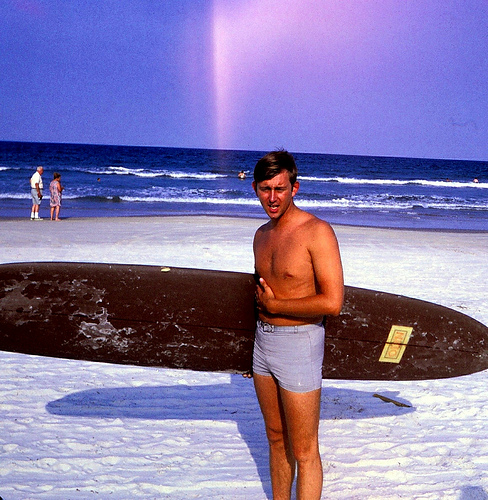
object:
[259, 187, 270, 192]
eye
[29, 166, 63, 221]
couple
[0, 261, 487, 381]
surfboard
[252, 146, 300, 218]
head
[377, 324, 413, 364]
sticker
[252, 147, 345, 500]
man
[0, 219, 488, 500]
sand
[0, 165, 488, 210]
wave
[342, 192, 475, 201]
wave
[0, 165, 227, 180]
wave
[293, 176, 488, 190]
wave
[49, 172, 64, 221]
woman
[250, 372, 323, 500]
legs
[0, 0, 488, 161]
sky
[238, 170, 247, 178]
person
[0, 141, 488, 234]
ocean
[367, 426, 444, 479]
footprints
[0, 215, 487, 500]
beach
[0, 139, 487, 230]
water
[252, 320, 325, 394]
shorts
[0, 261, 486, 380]
board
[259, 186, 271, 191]
eye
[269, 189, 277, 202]
nose